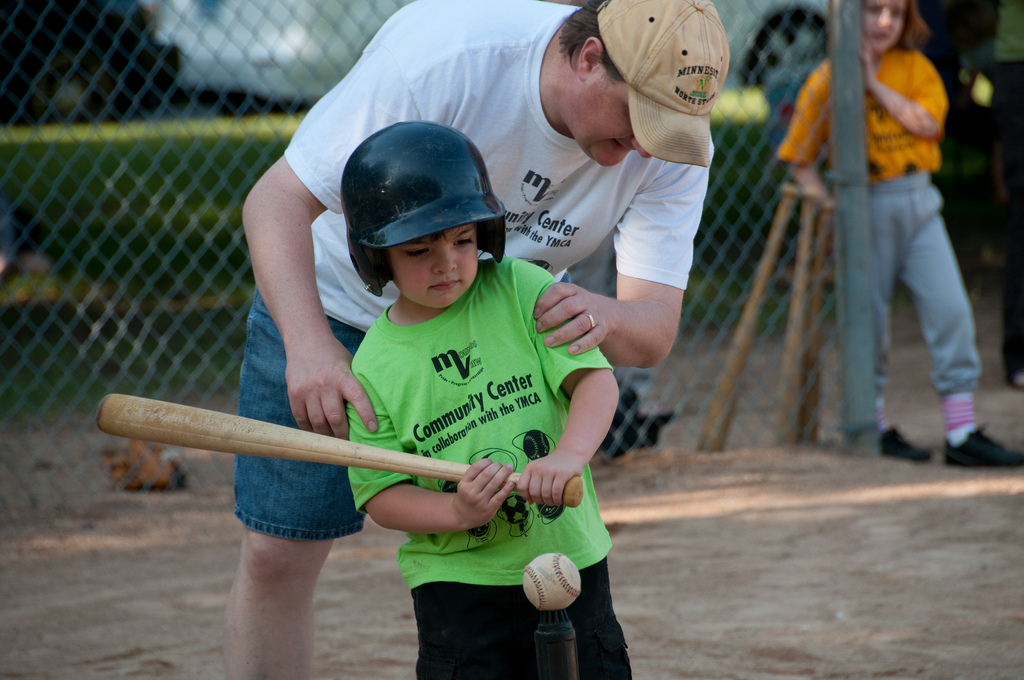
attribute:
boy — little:
[338, 117, 632, 677]